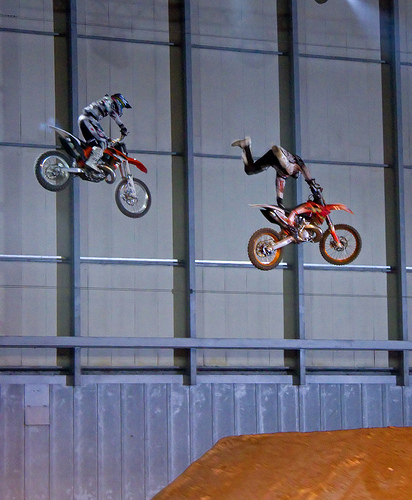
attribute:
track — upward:
[148, 425, 410, 498]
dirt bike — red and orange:
[245, 190, 362, 270]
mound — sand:
[197, 420, 348, 492]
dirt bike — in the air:
[78, 81, 140, 161]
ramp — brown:
[151, 421, 408, 495]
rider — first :
[229, 134, 310, 208]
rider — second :
[226, 127, 315, 210]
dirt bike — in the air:
[34, 121, 152, 219]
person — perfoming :
[231, 137, 321, 202]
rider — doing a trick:
[232, 128, 325, 209]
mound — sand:
[142, 419, 409, 498]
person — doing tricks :
[198, 117, 343, 199]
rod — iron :
[168, 2, 198, 369]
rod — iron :
[50, 7, 80, 387]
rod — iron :
[274, 7, 304, 384]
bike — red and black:
[34, 117, 151, 220]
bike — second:
[246, 177, 363, 271]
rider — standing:
[229, 131, 325, 215]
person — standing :
[77, 91, 130, 175]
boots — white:
[84, 147, 105, 179]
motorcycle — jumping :
[34, 117, 154, 219]